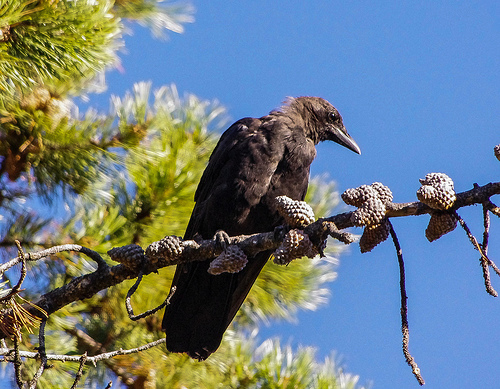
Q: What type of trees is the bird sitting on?
A: A pine tree branch.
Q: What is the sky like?
A: Blue and beautiful.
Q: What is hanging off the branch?
A: A long twig.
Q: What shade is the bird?
A: Black.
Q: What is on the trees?
A: Green branches.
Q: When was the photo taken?
A: Sunny day.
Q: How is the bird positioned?
A: Sitting.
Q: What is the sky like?
A: Clear.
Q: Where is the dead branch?
A: On tree.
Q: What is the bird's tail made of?
A: Feathers.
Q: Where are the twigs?
A: Pine tree.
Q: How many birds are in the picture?
A: 1.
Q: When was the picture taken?
A: Daytime.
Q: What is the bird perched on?
A: A tree limb.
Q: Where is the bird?
A: In a tree.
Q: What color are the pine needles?
A: Green.